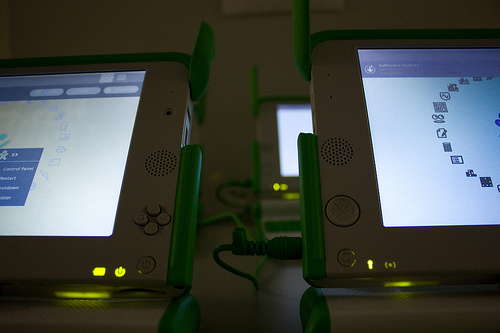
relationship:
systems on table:
[1, 30, 498, 291] [3, 160, 499, 328]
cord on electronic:
[217, 228, 299, 295] [284, 2, 498, 332]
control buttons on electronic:
[146, 201, 162, 217] [2, 54, 194, 288]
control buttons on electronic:
[154, 212, 170, 227] [2, 54, 194, 288]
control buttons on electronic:
[144, 219, 161, 235] [2, 54, 194, 288]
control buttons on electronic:
[133, 211, 152, 227] [2, 54, 194, 288]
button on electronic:
[114, 259, 127, 284] [0, 19, 215, 330]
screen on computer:
[1, 70, 150, 238] [0, 19, 223, 332]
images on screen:
[432, 75, 499, 190] [356, 46, 498, 228]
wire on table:
[199, 209, 254, 242] [137, 169, 419, 331]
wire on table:
[199, 176, 257, 241] [137, 169, 419, 331]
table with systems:
[188, 168, 311, 331] [354, 48, 497, 229]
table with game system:
[188, 168, 311, 331] [247, 64, 314, 241]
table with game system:
[188, 168, 311, 331] [1, 21, 216, 331]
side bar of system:
[295, 127, 325, 285] [354, 45, 495, 229]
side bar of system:
[291, 0, 311, 87] [354, 45, 495, 229]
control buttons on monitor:
[144, 221, 159, 235] [2, 51, 193, 295]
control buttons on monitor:
[157, 213, 170, 224] [2, 51, 193, 295]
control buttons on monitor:
[146, 203, 161, 215] [2, 51, 193, 295]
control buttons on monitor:
[135, 212, 148, 224] [2, 51, 193, 295]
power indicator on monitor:
[111, 265, 128, 280] [0, 18, 214, 330]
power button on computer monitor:
[133, 250, 157, 275] [0, 12, 217, 331]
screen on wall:
[1, 70, 150, 238] [58, 31, 143, 53]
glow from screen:
[377, 276, 439, 293] [304, 27, 499, 287]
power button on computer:
[135, 254, 158, 275] [2, 50, 197, 331]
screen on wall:
[1, 70, 150, 238] [258, 95, 310, 214]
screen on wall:
[1, 45, 175, 287] [267, 106, 327, 231]